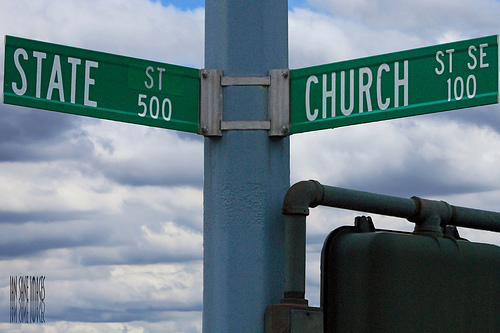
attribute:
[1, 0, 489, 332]
sky — blue, cloud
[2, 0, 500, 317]
clouds — white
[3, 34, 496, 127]
sigs — gree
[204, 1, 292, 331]
pole — blue, rough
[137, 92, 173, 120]
umbers — white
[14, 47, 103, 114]
words — white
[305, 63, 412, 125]
letters — white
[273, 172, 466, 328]
pipe — curved, threaded, shaped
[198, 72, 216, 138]
bolts — small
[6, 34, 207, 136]
sign — gree, white, flarig, raised, light, grey, preset, green, addressed, aimed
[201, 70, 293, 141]
metal — sign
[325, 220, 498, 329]
rod — curved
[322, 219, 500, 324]
box — green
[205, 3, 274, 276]
light — backed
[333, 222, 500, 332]
back — black